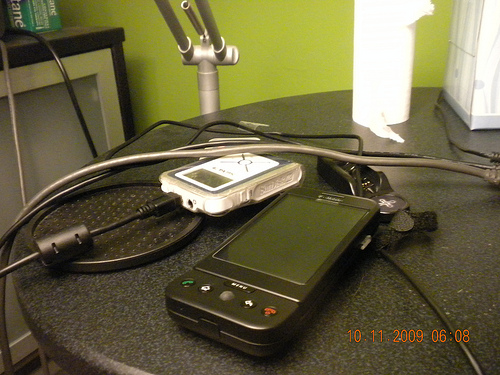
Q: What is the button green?
A: On.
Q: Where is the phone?
A: On table.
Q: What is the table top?
A: Marble.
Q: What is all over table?
A: Cords.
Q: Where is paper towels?
A: On table.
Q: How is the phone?
A: Off.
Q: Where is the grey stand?
A: Beside table.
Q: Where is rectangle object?
A: On table.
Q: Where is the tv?
A: Side of table.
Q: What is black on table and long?
A: Cords.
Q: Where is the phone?
A: Table.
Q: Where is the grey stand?
A: Side of table.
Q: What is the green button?
A: On.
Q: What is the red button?
A: Off.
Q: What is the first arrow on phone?
A: To left.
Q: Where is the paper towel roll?
A: On table.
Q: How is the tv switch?
A: Off.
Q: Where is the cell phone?
A: On the table.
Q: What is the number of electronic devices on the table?
A: 2.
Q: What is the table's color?
A: Black.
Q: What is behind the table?
A: Cabinet.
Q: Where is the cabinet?
A: Behind the table.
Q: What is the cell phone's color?
A: Black.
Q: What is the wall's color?
A: Green.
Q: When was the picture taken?
A: October 11, 2009.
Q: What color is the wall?
A: Green.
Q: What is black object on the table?
A: A phone.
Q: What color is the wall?
A: Green.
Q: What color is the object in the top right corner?
A: White.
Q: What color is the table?
A: Grey.